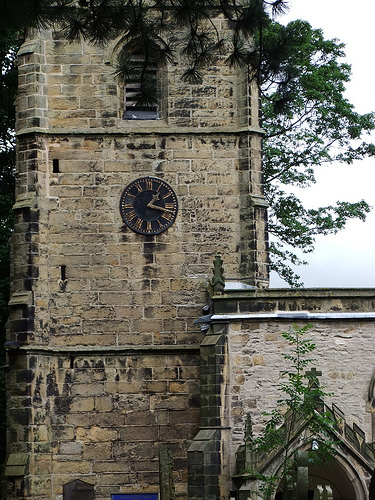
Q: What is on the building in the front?
A: Clock.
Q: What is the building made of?
A: Brick.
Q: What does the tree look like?
A: Tall and green.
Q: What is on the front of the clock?
A: Hands.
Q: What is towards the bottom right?
A: Door.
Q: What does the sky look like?
A: Cloudy.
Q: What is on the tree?
A: Leaves.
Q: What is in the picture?
A: Old worn stone church.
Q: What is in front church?
A: A short tree.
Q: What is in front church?
A: A pine tree branch.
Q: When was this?
A: Daytime.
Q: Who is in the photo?
A: Nobody.